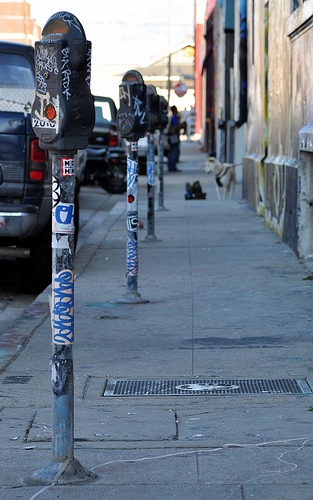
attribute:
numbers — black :
[30, 118, 61, 132]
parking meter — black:
[31, 9, 94, 487]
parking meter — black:
[112, 68, 152, 304]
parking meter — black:
[152, 92, 168, 212]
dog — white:
[203, 155, 239, 202]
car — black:
[79, 95, 123, 186]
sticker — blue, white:
[50, 202, 75, 235]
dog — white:
[202, 159, 245, 202]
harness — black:
[222, 154, 246, 183]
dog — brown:
[202, 156, 235, 202]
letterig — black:
[61, 158, 74, 174]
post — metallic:
[49, 154, 78, 460]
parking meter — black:
[141, 84, 163, 242]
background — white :
[62, 158, 65, 172]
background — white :
[55, 116, 60, 131]